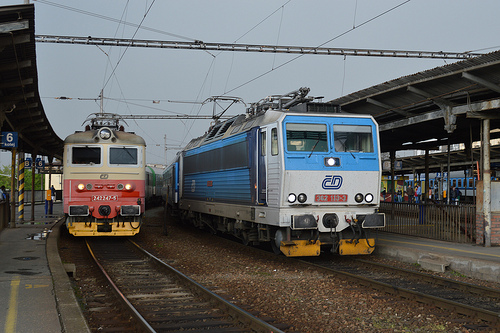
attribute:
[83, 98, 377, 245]
trains — approaching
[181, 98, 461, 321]
train — blue, silver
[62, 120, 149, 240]
train — beige, red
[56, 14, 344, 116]
wires — electrical, connected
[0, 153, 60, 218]
pole — black, yellow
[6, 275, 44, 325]
barrier lines — yellow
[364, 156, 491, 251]
railing — metal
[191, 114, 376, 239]
train — blue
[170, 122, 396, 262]
train — blue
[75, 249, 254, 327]
track — railroad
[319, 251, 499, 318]
track — railroad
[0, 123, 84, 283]
platform — six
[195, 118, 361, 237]
train — blue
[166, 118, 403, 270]
train — blue, white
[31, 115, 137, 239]
train — white, red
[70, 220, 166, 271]
train — yellow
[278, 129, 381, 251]
lights — on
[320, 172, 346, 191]
lettering — blue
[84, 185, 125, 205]
numbers — white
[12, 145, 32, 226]
pole — striped, blue, yellow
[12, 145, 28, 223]
pole — black, yellow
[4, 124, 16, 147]
sign — blue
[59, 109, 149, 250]
train — red, white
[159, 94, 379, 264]
train — white, blue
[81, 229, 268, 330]
train tracks — gray, brown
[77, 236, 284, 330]
train tracks — brown, gray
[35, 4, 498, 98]
wires — black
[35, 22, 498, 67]
wires — black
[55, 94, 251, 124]
wires — black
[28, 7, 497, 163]
sky — clear, overcast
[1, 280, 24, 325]
line — solid, yellow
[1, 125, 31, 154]
sign — blue